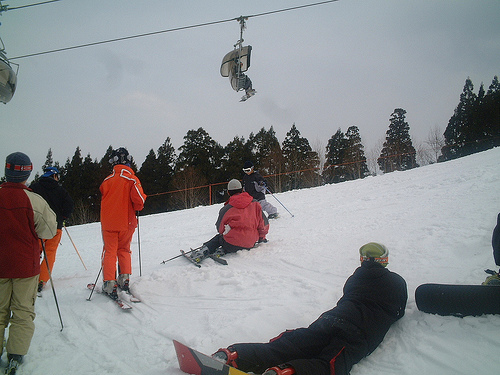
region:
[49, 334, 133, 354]
ski tracks in the snow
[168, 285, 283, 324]
ski tracks on top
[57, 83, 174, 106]
storm clouds in the sky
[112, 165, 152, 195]
white lining on orange parka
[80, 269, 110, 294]
large ski pole in skier's hand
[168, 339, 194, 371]
red bottom snow board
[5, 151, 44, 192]
orange and gray ski cap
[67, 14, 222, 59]
overhead line for snow lift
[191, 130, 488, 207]
cluster of green evergreen trees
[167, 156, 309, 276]
skier laying in the snow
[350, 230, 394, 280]
a green and orange hat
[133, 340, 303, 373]
snow board and boots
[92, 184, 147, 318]
orange and white outfit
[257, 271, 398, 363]
black and red outfit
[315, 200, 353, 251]
patch of white snow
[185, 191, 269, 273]
red and black jacket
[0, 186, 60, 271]
red and tan jacket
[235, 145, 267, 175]
black hat and white goggles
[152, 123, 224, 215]
green trees and bare trees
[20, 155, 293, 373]
a group of people skiing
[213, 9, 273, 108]
Person riding on a ski lift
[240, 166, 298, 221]
Person skiing down a hill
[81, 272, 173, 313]
Skis on a skiers feet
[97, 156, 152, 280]
Orange ski suit on a person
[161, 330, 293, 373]
Snowboard on a persons feet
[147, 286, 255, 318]
Tracks in the snow from skis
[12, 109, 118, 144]
Grey sky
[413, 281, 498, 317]
Bottom of a snowboard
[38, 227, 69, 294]
Orange ski pants on a person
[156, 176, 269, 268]
Skier sitting in the snow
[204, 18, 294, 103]
Person riding a ski lift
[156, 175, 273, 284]
Skier sitting on the snow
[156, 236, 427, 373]
Snowboarder laying on the snow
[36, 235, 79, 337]
Ski pole in a skiers hand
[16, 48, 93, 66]
Cable for the ski lift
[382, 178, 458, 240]
Snow on the ground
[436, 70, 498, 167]
Trees on the side of the ski slope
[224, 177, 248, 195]
Grey ski cap on a person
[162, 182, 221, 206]
Fencing to mark off ski area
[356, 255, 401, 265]
Band on a persons head for holding goggles in place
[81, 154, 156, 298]
an orange snow suit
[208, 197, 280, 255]
a red snow jacket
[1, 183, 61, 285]
maroon and tan snow jacket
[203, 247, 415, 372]
a black snow jacket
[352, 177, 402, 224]
this is white snow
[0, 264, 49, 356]
these are tan pants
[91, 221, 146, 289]
these are orange pants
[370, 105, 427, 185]
this is a tree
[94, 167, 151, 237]
this is an orange jacket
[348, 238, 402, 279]
this is a khaki hat.